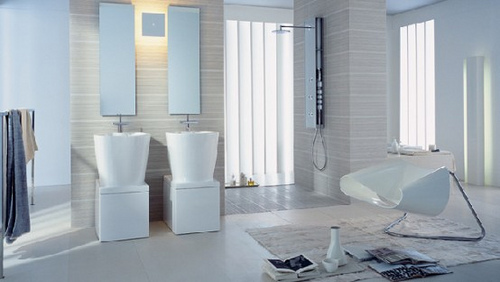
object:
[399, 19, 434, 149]
window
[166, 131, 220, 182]
sink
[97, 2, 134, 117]
white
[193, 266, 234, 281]
white floor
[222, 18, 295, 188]
door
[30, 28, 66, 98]
white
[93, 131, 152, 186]
sink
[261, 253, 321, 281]
book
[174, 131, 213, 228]
white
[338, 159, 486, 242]
chair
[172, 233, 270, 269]
floor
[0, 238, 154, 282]
floor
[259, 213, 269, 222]
part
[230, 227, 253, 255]
part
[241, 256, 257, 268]
part